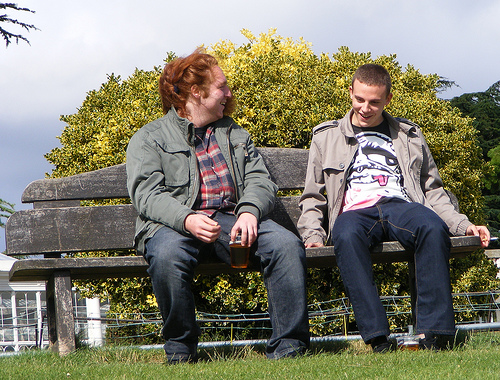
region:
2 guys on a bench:
[15, 39, 492, 356]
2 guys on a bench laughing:
[42, 49, 490, 368]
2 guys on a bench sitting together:
[19, 43, 477, 375]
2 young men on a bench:
[94, 40, 479, 360]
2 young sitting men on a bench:
[98, 39, 485, 367]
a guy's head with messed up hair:
[155, 41, 242, 141]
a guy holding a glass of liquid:
[129, 34, 317, 378]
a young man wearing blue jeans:
[297, 57, 484, 358]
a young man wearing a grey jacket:
[304, 59, 478, 260]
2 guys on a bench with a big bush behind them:
[42, 18, 474, 369]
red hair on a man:
[159, 52, 240, 125]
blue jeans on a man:
[141, 211, 313, 357]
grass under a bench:
[1, 329, 497, 379]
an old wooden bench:
[5, 141, 489, 355]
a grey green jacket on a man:
[124, 104, 282, 257]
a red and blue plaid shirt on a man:
[188, 126, 238, 220]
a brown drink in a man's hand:
[223, 231, 254, 276]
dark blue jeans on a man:
[329, 200, 466, 346]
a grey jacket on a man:
[294, 114, 473, 248]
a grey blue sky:
[0, 1, 497, 214]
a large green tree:
[42, 33, 487, 330]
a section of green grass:
[0, 323, 499, 377]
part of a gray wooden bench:
[2, 145, 480, 365]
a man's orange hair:
[158, 50, 240, 117]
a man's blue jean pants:
[333, 196, 455, 349]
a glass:
[229, 232, 252, 271]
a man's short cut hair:
[352, 63, 390, 95]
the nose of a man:
[222, 84, 231, 95]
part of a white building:
[0, 258, 110, 351]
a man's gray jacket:
[124, 102, 281, 246]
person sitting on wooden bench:
[128, 56, 299, 317]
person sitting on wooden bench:
[305, 53, 497, 337]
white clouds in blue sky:
[72, 15, 112, 55]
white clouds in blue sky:
[20, 66, 50, 87]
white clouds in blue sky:
[397, 8, 492, 48]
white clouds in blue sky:
[125, 26, 157, 57]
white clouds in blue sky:
[284, 13, 332, 34]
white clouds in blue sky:
[374, 9, 408, 36]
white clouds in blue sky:
[404, 12, 465, 62]